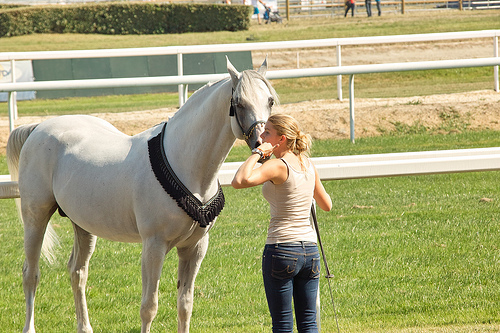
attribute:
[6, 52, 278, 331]
horse — white, standing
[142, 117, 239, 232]
collar — black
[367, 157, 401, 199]
ground — white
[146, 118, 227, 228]
girdle — brown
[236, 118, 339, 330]
woman — standing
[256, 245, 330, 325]
jeans — blue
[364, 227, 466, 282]
grass — green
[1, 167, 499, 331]
grass — green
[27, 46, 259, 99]
barricade — green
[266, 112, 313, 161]
hair — brown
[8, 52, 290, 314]
horse — white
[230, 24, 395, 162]
rails — white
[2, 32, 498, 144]
railings — white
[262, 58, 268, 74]
ear — pointed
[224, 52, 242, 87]
ear — pointed